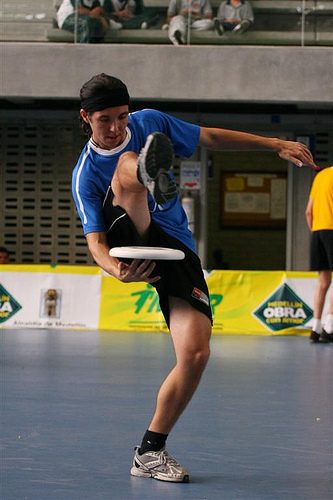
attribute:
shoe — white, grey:
[136, 130, 178, 202]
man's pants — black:
[98, 184, 211, 327]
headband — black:
[76, 92, 134, 111]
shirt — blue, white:
[65, 103, 200, 242]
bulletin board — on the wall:
[219, 170, 288, 229]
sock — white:
[306, 312, 323, 336]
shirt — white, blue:
[71, 109, 200, 246]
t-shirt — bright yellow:
[306, 165, 331, 232]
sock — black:
[132, 424, 169, 453]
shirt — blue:
[55, 132, 250, 241]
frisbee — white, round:
[105, 241, 186, 262]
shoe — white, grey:
[129, 443, 191, 483]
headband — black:
[80, 84, 129, 113]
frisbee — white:
[107, 246, 184, 259]